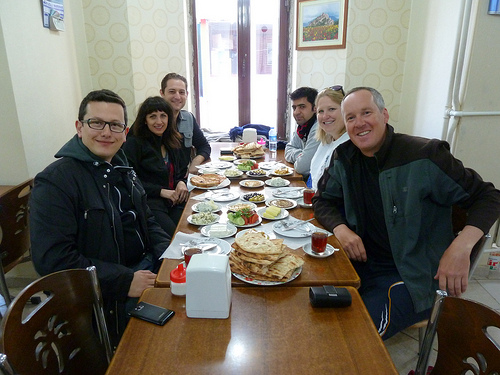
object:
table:
[153, 142, 363, 286]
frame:
[189, 0, 291, 139]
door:
[190, 0, 288, 146]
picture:
[295, 0, 348, 52]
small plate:
[296, 198, 313, 209]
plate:
[227, 265, 303, 286]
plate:
[200, 223, 237, 239]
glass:
[310, 229, 329, 255]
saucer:
[302, 242, 339, 258]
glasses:
[81, 118, 127, 133]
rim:
[87, 117, 126, 133]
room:
[5, 7, 497, 374]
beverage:
[310, 229, 329, 255]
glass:
[303, 187, 316, 206]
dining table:
[105, 140, 401, 375]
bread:
[229, 228, 306, 282]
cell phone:
[128, 300, 176, 327]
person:
[310, 86, 497, 339]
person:
[159, 73, 212, 177]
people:
[27, 90, 173, 355]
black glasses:
[81, 118, 127, 133]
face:
[79, 100, 125, 157]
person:
[122, 97, 188, 237]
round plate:
[257, 205, 290, 221]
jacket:
[25, 133, 172, 357]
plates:
[272, 219, 318, 239]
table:
[106, 285, 399, 374]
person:
[310, 84, 352, 194]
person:
[283, 87, 322, 175]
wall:
[356, 18, 404, 60]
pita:
[223, 228, 309, 291]